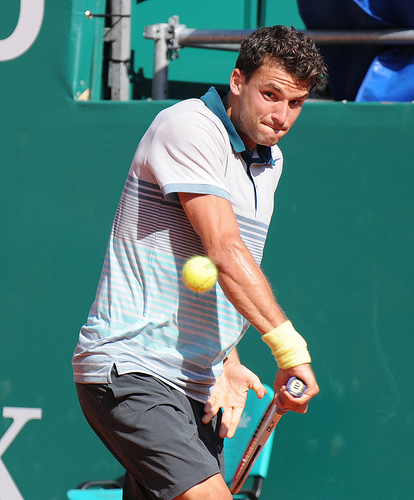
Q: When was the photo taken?
A: Day time.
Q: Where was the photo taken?
A: At a tennis match.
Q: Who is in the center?
A: A man.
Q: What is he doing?
A: Playing tennis.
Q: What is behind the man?
A: Stands.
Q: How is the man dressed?
A: Shorts and short-sleeve top.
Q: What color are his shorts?
A: Gray.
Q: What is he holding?
A: A tennis racquet.